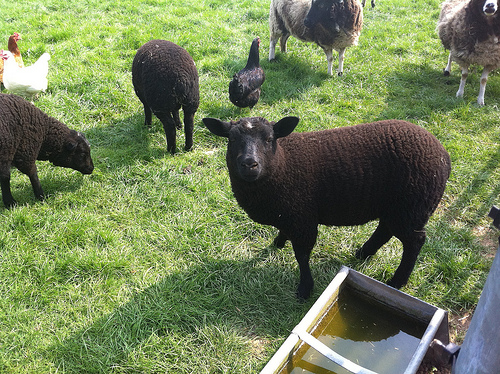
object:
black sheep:
[131, 38, 201, 154]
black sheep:
[0, 93, 95, 209]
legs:
[443, 47, 491, 100]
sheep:
[266, 0, 365, 79]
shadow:
[373, 59, 500, 136]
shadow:
[229, 52, 331, 107]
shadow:
[72, 113, 167, 171]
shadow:
[0, 174, 82, 212]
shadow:
[416, 151, 498, 317]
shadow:
[50, 77, 95, 95]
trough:
[263, 265, 449, 374]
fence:
[250, 264, 464, 374]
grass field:
[0, 0, 500, 374]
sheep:
[432, 0, 500, 107]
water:
[270, 279, 429, 374]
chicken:
[229, 35, 266, 112]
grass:
[0, 0, 500, 374]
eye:
[265, 135, 274, 143]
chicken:
[0, 48, 52, 104]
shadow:
[0, 250, 366, 374]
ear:
[272, 115, 300, 139]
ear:
[201, 117, 231, 139]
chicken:
[0, 32, 23, 87]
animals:
[0, 0, 500, 295]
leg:
[289, 229, 316, 290]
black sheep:
[202, 115, 452, 304]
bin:
[255, 263, 450, 374]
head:
[9, 32, 22, 43]